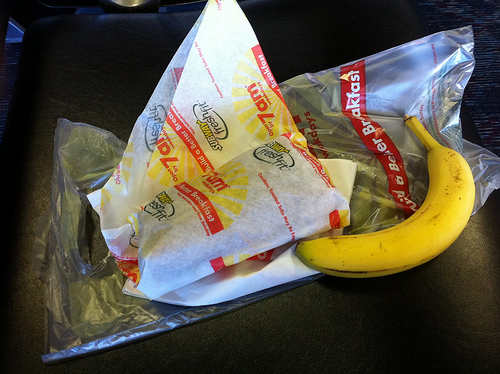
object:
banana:
[294, 114, 482, 280]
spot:
[459, 197, 462, 200]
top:
[403, 114, 439, 153]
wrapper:
[85, 0, 349, 302]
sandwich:
[136, 134, 350, 285]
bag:
[12, 24, 499, 364]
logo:
[192, 100, 229, 151]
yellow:
[178, 151, 205, 181]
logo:
[344, 70, 418, 212]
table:
[0, 0, 499, 374]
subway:
[196, 120, 224, 152]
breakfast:
[191, 191, 215, 222]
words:
[167, 109, 182, 131]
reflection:
[364, 43, 476, 132]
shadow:
[340, 277, 487, 369]